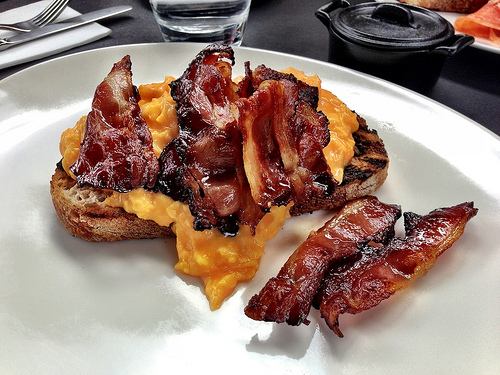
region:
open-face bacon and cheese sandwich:
[47, 37, 392, 279]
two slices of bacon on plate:
[243, 196, 478, 341]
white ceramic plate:
[1, 41, 499, 373]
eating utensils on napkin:
[0, 0, 134, 70]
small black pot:
[315, 0, 475, 96]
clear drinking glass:
[148, 0, 253, 45]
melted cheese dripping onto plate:
[169, 225, 288, 312]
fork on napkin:
[1, 1, 73, 32]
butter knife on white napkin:
[0, 3, 137, 51]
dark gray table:
[1, 0, 497, 135]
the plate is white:
[186, 335, 203, 352]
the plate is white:
[196, 348, 211, 363]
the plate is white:
[202, 353, 211, 362]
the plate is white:
[207, 330, 222, 355]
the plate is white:
[222, 345, 231, 355]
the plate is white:
[222, 340, 235, 372]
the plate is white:
[212, 363, 222, 374]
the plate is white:
[207, 366, 213, 373]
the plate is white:
[203, 348, 215, 365]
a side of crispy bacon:
[245, 201, 465, 322]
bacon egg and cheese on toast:
[32, 95, 399, 206]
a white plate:
[42, 271, 187, 373]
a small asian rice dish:
[312, 1, 471, 111]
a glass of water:
[148, 0, 262, 55]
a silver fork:
[16, 0, 68, 22]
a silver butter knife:
[16, 1, 155, 37]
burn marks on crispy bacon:
[397, 206, 425, 226]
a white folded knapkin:
[5, 23, 136, 45]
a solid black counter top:
[260, 9, 302, 41]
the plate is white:
[364, 331, 384, 372]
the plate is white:
[382, 343, 399, 362]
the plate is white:
[404, 343, 416, 366]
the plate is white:
[374, 348, 384, 370]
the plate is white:
[387, 347, 392, 372]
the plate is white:
[388, 350, 396, 364]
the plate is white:
[370, 356, 381, 373]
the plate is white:
[395, 328, 410, 348]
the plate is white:
[402, 348, 403, 353]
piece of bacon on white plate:
[282, 202, 426, 308]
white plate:
[14, 45, 498, 365]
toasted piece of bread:
[60, 160, 327, 215]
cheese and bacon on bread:
[59, 80, 344, 209]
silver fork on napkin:
[14, 2, 107, 43]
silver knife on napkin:
[6, 0, 136, 38]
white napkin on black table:
[4, 6, 111, 46]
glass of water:
[158, 0, 240, 33]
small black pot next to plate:
[322, 3, 462, 81]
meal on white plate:
[22, 47, 468, 357]